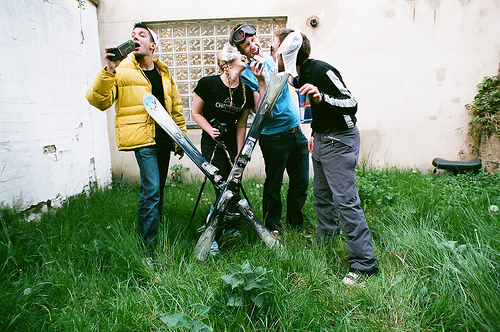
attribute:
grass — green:
[69, 236, 163, 309]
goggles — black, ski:
[228, 25, 300, 39]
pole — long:
[189, 166, 223, 225]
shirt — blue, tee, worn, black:
[240, 60, 332, 143]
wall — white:
[359, 18, 485, 118]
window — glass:
[178, 30, 232, 71]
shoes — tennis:
[300, 245, 390, 296]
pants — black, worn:
[185, 127, 248, 183]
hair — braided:
[213, 53, 254, 103]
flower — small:
[478, 195, 499, 223]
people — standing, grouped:
[83, 27, 376, 213]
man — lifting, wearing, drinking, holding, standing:
[271, 72, 310, 134]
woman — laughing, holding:
[209, 42, 261, 103]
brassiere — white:
[273, 29, 317, 74]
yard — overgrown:
[64, 226, 412, 331]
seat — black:
[426, 148, 493, 198]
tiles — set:
[153, 23, 234, 77]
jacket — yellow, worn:
[84, 62, 232, 156]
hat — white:
[216, 46, 243, 69]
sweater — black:
[282, 76, 387, 151]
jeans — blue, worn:
[136, 149, 190, 264]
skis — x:
[126, 88, 320, 275]